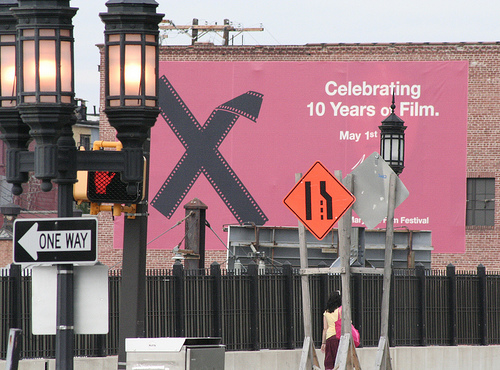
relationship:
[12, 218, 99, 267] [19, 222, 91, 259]
traffic sign with an arrow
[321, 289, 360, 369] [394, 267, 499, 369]
woman walking on sidewalk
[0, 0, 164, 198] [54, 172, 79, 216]
street lights on a light pole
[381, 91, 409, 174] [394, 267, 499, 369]
street light on sidewalk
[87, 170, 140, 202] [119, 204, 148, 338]
crosswalk signal on a pole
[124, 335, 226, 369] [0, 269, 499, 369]
box on street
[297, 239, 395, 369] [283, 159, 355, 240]
pole with sign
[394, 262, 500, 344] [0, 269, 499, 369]
metal fence along street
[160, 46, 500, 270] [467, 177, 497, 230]
building with a window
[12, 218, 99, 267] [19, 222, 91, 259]
sign points left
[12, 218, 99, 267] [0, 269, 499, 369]
traffic sign on street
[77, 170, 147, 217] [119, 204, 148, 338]
crosswalk signal on a pole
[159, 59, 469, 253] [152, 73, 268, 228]
sign has an x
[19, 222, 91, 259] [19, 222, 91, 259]
traffic sign points left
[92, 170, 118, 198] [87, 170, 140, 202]
hand on crosswalk signal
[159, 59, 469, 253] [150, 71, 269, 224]
billboard has film strips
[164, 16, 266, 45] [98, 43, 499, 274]
power lines behind building